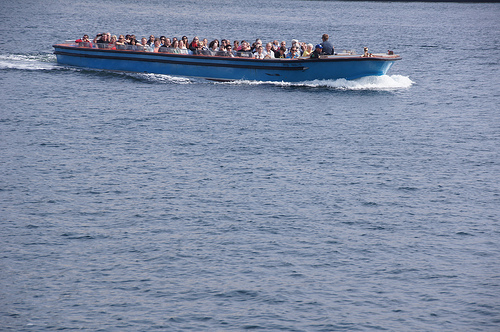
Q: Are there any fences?
A: No, there are no fences.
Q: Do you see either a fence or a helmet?
A: No, there are no fences or helmets.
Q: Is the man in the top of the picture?
A: Yes, the man is in the top of the image.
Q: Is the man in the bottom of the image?
A: No, the man is in the top of the image.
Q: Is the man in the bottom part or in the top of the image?
A: The man is in the top of the image.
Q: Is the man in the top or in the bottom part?
A: The man is in the top of the image.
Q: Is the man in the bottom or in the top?
A: The man is in the top of the image.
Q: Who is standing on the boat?
A: The man is standing on the boat.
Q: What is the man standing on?
A: The man is standing on the boat.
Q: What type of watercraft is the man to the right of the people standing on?
A: The man is standing on the boat.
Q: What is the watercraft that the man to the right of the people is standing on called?
A: The watercraft is a boat.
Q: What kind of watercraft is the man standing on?
A: The man is standing on the boat.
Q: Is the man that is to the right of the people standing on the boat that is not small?
A: Yes, the man is standing on the boat.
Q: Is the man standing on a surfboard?
A: No, the man is standing on the boat.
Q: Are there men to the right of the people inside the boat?
A: Yes, there is a man to the right of the people.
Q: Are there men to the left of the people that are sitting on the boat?
A: No, the man is to the right of the people.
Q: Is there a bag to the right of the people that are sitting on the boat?
A: No, there is a man to the right of the people.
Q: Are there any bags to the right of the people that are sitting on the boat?
A: No, there is a man to the right of the people.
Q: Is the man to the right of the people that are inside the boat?
A: Yes, the man is to the right of the people.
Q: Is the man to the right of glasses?
A: No, the man is to the right of the people.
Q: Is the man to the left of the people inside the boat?
A: No, the man is to the right of the people.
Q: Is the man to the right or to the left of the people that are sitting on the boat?
A: The man is to the right of the people.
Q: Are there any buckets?
A: No, there are no buckets.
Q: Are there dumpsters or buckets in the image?
A: No, there are no buckets or dumpsters.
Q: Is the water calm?
A: Yes, the water is calm.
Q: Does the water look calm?
A: Yes, the water is calm.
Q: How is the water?
A: The water is calm.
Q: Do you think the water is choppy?
A: No, the water is calm.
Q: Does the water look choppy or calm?
A: The water is calm.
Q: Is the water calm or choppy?
A: The water is calm.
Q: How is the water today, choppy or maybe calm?
A: The water is calm.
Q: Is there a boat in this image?
A: Yes, there is a boat.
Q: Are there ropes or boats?
A: Yes, there is a boat.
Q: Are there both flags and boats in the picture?
A: No, there is a boat but no flags.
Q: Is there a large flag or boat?
A: Yes, there is a large boat.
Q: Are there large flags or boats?
A: Yes, there is a large boat.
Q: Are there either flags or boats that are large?
A: Yes, the boat is large.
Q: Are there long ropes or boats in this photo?
A: Yes, there is a long boat.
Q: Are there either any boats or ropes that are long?
A: Yes, the boat is long.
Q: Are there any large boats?
A: Yes, there is a large boat.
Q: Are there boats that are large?
A: Yes, there is a boat that is large.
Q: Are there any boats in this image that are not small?
A: Yes, there is a large boat.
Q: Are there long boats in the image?
A: Yes, there is a long boat.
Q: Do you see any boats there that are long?
A: Yes, there is a boat that is long.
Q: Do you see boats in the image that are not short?
A: Yes, there is a long boat.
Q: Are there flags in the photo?
A: No, there are no flags.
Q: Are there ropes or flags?
A: No, there are no flags or ropes.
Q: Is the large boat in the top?
A: Yes, the boat is in the top of the image.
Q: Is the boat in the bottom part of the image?
A: No, the boat is in the top of the image.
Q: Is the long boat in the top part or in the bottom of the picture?
A: The boat is in the top of the image.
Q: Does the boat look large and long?
A: Yes, the boat is large and long.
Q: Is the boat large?
A: Yes, the boat is large.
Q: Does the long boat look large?
A: Yes, the boat is large.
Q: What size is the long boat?
A: The boat is large.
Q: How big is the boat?
A: The boat is large.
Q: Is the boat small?
A: No, the boat is large.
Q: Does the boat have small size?
A: No, the boat is large.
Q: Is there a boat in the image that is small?
A: No, there is a boat but it is large.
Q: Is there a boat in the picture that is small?
A: No, there is a boat but it is large.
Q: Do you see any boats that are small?
A: No, there is a boat but it is large.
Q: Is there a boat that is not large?
A: No, there is a boat but it is large.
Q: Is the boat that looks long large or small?
A: The boat is large.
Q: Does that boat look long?
A: Yes, the boat is long.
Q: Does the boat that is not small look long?
A: Yes, the boat is long.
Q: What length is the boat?
A: The boat is long.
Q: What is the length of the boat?
A: The boat is long.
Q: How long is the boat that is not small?
A: The boat is long.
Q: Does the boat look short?
A: No, the boat is long.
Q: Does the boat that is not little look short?
A: No, the boat is long.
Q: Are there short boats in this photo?
A: No, there is a boat but it is long.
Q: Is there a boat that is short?
A: No, there is a boat but it is long.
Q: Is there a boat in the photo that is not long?
A: No, there is a boat but it is long.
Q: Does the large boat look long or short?
A: The boat is long.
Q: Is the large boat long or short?
A: The boat is long.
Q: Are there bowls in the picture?
A: No, there are no bowls.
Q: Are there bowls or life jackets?
A: No, there are no bowls or life jackets.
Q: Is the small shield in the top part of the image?
A: Yes, the shield is in the top of the image.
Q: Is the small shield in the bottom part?
A: No, the shield is in the top of the image.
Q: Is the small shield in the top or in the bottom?
A: The shield is in the top of the image.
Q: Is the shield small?
A: Yes, the shield is small.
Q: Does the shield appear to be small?
A: Yes, the shield is small.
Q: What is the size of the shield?
A: The shield is small.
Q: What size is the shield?
A: The shield is small.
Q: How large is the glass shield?
A: The shield is small.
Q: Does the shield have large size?
A: No, the shield is small.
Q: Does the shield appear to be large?
A: No, the shield is small.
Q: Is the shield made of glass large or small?
A: The shield is small.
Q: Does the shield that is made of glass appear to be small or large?
A: The shield is small.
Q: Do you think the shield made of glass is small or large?
A: The shield is small.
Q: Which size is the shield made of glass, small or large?
A: The shield is small.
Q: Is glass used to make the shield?
A: Yes, the shield is made of glass.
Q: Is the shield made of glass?
A: Yes, the shield is made of glass.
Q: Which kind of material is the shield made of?
A: The shield is made of glass.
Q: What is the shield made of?
A: The shield is made of glass.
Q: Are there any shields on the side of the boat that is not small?
A: Yes, there is a shield on the side of the boat.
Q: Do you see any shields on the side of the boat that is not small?
A: Yes, there is a shield on the side of the boat.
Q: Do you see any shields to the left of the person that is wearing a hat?
A: Yes, there is a shield to the left of the person.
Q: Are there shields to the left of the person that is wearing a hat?
A: Yes, there is a shield to the left of the person.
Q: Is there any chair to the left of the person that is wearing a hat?
A: No, there is a shield to the left of the person.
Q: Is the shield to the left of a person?
A: Yes, the shield is to the left of a person.